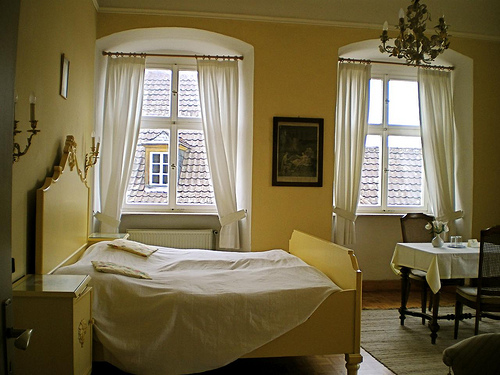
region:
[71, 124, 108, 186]
fancy light with three bulbs on the wall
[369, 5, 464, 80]
beautiful light hanging from the celing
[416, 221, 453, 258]
bouquet of white roses in a vase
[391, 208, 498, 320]
kitchen chairs pushed up to the table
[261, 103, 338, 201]
picture with a wooden frame on the wall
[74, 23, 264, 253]
white curtains drape the windows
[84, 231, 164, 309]
pillows lay atop the bed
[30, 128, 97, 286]
fancy white headboard leans against the wall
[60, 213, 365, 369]
bed is made with a white sheet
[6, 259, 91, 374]
end table is beside the bed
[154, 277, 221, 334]
the bed is white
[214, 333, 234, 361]
the bed is white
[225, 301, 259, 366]
the bed is white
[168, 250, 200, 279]
the bed is white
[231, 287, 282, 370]
the bed is white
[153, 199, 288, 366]
the bed is white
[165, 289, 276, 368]
the bed is white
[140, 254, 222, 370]
the bed is white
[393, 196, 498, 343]
Table and two chairs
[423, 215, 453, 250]
Flowers in a small vase on the table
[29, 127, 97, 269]
Yellow wooden headboard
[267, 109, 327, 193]
Painting on the wall between two windows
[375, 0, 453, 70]
Chandelier hanging from the ceiling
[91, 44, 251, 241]
Window with white curtains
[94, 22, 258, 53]
Arched moulding over window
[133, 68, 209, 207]
Roof of the building outside the window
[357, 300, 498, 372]
Rug on the floor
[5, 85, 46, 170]
Sconse on left wall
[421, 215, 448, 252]
white vase on table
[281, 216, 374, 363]
foot board at end of bed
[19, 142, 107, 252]
headboard at top of bed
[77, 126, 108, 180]
sconce on back wall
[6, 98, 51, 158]
sconce on back wall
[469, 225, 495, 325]
chair pushed up at table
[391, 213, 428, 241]
chair pushed to table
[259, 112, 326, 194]
print hanging on wall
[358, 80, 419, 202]
window in bedroom with panes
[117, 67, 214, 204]
window in bedroom with panes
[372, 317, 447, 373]
green rug on the floor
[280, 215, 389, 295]
yellow frame on bed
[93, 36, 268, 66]
large rod on top of window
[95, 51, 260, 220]
white drapes on rod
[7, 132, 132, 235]
yellow bed head flush with the wall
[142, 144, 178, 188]
white window on the white house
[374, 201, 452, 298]
black chair around the table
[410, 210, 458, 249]
white vase on table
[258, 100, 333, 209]
picture on the wall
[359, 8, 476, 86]
gold chandalier in the ceiling